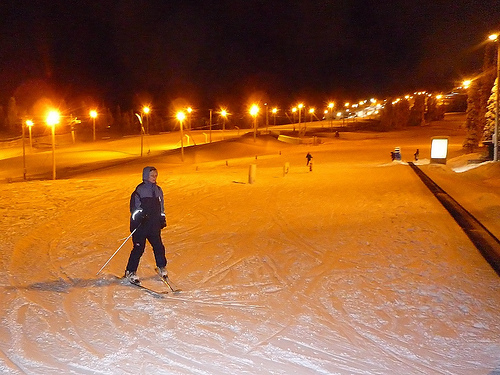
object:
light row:
[23, 76, 477, 181]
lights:
[42, 107, 64, 129]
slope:
[1, 112, 500, 375]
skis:
[108, 271, 170, 295]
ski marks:
[329, 318, 352, 340]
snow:
[0, 212, 500, 373]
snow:
[374, 72, 500, 161]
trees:
[412, 147, 420, 161]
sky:
[0, 0, 500, 130]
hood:
[142, 165, 157, 185]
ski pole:
[95, 221, 144, 278]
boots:
[124, 268, 143, 286]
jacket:
[128, 165, 167, 233]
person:
[305, 151, 314, 166]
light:
[40, 105, 65, 181]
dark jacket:
[305, 153, 313, 160]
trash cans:
[390, 146, 402, 161]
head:
[142, 165, 158, 184]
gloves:
[140, 213, 150, 226]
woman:
[122, 164, 170, 286]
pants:
[125, 229, 169, 273]